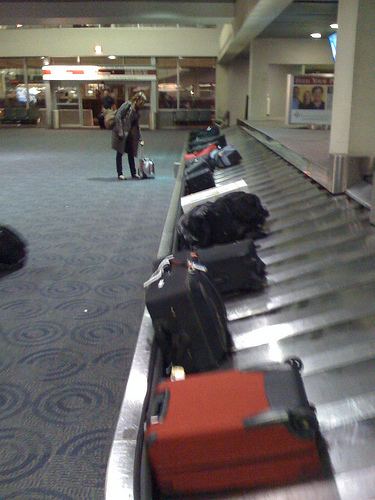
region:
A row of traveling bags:
[138, 119, 321, 484]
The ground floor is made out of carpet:
[27, 216, 112, 449]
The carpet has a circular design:
[20, 271, 103, 484]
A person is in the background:
[95, 80, 117, 125]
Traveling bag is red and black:
[132, 350, 334, 493]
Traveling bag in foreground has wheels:
[135, 335, 346, 488]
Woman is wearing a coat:
[108, 94, 146, 166]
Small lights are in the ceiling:
[297, 12, 336, 42]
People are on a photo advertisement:
[281, 70, 337, 130]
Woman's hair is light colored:
[122, 88, 152, 128]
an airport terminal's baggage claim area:
[17, 16, 370, 496]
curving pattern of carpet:
[8, 282, 103, 458]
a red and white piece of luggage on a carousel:
[124, 353, 354, 497]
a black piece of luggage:
[132, 248, 237, 367]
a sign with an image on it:
[278, 64, 343, 137]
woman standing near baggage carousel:
[99, 86, 235, 201]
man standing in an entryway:
[39, 59, 161, 132]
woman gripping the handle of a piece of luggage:
[113, 85, 161, 182]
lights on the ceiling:
[298, 6, 338, 51]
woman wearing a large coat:
[105, 84, 152, 159]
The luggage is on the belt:
[179, 110, 308, 406]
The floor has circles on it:
[24, 279, 142, 474]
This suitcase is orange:
[156, 386, 344, 486]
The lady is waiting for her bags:
[114, 82, 177, 209]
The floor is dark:
[47, 282, 195, 468]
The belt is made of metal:
[255, 245, 356, 430]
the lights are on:
[42, 21, 141, 102]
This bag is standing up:
[142, 262, 238, 390]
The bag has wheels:
[253, 343, 323, 490]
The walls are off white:
[240, 72, 361, 162]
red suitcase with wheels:
[147, 357, 336, 493]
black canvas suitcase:
[147, 250, 241, 372]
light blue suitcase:
[207, 145, 243, 168]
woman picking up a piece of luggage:
[112, 88, 161, 184]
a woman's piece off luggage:
[142, 146, 158, 181]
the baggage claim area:
[166, 32, 372, 493]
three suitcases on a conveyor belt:
[150, 235, 335, 489]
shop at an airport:
[1, 59, 208, 122]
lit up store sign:
[43, 66, 157, 80]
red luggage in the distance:
[183, 141, 221, 165]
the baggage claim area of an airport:
[9, 18, 359, 488]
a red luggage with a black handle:
[139, 364, 343, 486]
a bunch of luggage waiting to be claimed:
[163, 122, 314, 432]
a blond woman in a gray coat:
[110, 84, 145, 183]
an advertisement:
[283, 65, 336, 129]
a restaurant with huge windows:
[6, 57, 210, 124]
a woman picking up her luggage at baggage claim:
[106, 80, 167, 187]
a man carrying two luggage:
[93, 85, 117, 128]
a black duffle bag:
[181, 190, 290, 235]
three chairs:
[170, 106, 219, 128]